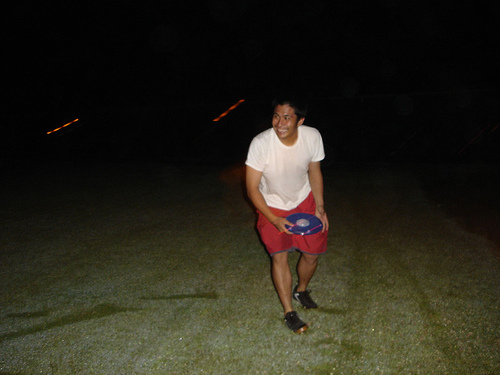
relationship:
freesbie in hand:
[272, 209, 332, 236] [272, 214, 292, 232]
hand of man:
[272, 214, 292, 232] [249, 92, 330, 337]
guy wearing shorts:
[245, 99, 332, 334] [261, 213, 332, 253]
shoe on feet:
[285, 311, 310, 333] [280, 289, 328, 338]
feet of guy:
[280, 289, 328, 338] [245, 99, 332, 334]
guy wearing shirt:
[245, 99, 332, 334] [247, 126, 327, 209]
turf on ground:
[340, 332, 396, 356] [102, 311, 422, 366]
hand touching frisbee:
[313, 208, 333, 234] [285, 207, 329, 241]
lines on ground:
[108, 280, 350, 362] [1, 160, 476, 360]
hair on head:
[263, 90, 307, 123] [267, 63, 303, 168]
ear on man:
[293, 102, 306, 134] [194, 76, 421, 345]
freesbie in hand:
[272, 209, 332, 236] [296, 134, 340, 264]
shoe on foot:
[285, 311, 310, 333] [263, 268, 343, 350]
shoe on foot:
[244, 280, 352, 360] [255, 254, 388, 370]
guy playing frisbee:
[245, 99, 332, 334] [263, 192, 371, 272]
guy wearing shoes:
[245, 99, 332, 334] [253, 276, 353, 344]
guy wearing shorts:
[245, 99, 332, 334] [232, 168, 369, 276]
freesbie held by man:
[269, 179, 380, 296] [181, 77, 398, 347]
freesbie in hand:
[269, 201, 357, 259] [228, 132, 325, 310]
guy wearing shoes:
[202, 76, 420, 354] [245, 257, 365, 373]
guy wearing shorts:
[245, 99, 332, 334] [224, 180, 457, 304]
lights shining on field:
[37, 112, 90, 135] [29, 60, 239, 310]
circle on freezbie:
[291, 215, 313, 226] [292, 210, 316, 229]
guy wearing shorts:
[245, 99, 332, 334] [260, 199, 327, 252]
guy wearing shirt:
[245, 99, 332, 334] [245, 130, 321, 210]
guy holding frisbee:
[245, 99, 332, 334] [283, 209, 322, 232]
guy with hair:
[245, 99, 332, 334] [265, 90, 300, 110]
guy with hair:
[245, 99, 332, 334] [283, 95, 303, 102]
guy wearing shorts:
[245, 99, 332, 334] [255, 190, 325, 254]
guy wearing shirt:
[245, 99, 332, 334] [252, 133, 319, 205]